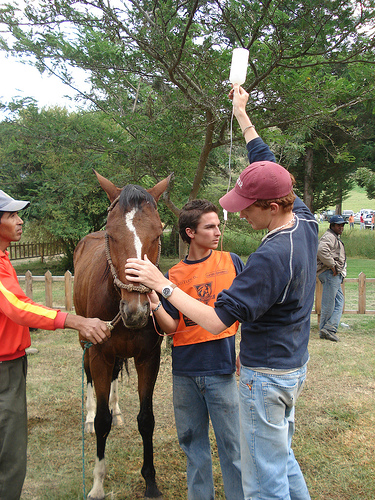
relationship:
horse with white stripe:
[65, 165, 193, 395] [124, 192, 164, 285]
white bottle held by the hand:
[215, 32, 264, 102] [224, 91, 279, 136]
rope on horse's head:
[95, 239, 129, 288] [97, 176, 189, 322]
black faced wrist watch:
[158, 287, 170, 299] [139, 257, 200, 330]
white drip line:
[208, 136, 236, 159] [204, 104, 240, 238]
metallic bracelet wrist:
[233, 94, 267, 143] [224, 91, 279, 136]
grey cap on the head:
[9, 182, 52, 209] [3, 207, 39, 275]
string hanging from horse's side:
[62, 330, 105, 401] [69, 233, 128, 351]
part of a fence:
[25, 235, 45, 254] [10, 240, 70, 278]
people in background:
[341, 211, 368, 242] [357, 200, 367, 210]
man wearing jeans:
[196, 171, 326, 399] [251, 355, 331, 487]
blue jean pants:
[219, 381, 223, 407] [182, 351, 275, 496]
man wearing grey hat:
[196, 171, 326, 399] [1, 170, 41, 239]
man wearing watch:
[196, 171, 326, 399] [139, 257, 200, 330]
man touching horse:
[196, 171, 326, 399] [65, 165, 193, 395]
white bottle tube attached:
[208, 136, 236, 159] [215, 57, 262, 224]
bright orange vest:
[209, 261, 224, 272] [151, 226, 239, 350]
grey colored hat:
[9, 182, 52, 209] [204, 153, 308, 222]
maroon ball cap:
[205, 161, 281, 194] [222, 127, 317, 220]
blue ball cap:
[219, 381, 223, 407] [222, 127, 317, 220]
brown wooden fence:
[43, 271, 51, 301] [10, 240, 70, 278]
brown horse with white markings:
[61, 174, 176, 305] [119, 198, 149, 305]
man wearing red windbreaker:
[196, 171, 326, 399] [1, 214, 53, 359]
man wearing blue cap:
[196, 171, 326, 399] [313, 195, 371, 236]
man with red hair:
[196, 171, 326, 399] [240, 190, 315, 211]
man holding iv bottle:
[196, 171, 326, 399] [204, 36, 271, 141]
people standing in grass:
[341, 211, 368, 242] [352, 252, 370, 286]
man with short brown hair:
[196, 171, 326, 399] [157, 198, 209, 222]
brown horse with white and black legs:
[61, 174, 176, 305] [47, 350, 171, 496]